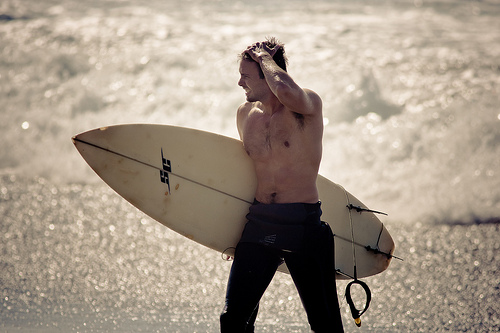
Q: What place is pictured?
A: It is an ocean.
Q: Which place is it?
A: It is an ocean.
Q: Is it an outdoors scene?
A: Yes, it is outdoors.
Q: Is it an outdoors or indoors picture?
A: It is outdoors.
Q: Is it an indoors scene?
A: No, it is outdoors.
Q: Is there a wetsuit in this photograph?
A: Yes, there is a wetsuit.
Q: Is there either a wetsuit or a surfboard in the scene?
A: Yes, there is a wetsuit.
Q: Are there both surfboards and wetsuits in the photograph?
A: Yes, there are both a wetsuit and a surfboard.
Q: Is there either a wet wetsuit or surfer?
A: Yes, there is a wet wetsuit.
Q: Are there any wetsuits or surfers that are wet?
A: Yes, the wetsuit is wet.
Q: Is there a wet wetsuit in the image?
A: Yes, there is a wet wetsuit.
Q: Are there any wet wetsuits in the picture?
A: Yes, there is a wet wetsuit.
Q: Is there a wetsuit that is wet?
A: Yes, there is a wetsuit that is wet.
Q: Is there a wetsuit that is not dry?
A: Yes, there is a wet wetsuit.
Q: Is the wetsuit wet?
A: Yes, the wetsuit is wet.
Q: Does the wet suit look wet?
A: Yes, the wet suit is wet.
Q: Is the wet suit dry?
A: No, the wet suit is wet.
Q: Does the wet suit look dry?
A: No, the wet suit is wet.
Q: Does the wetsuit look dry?
A: No, the wetsuit is wet.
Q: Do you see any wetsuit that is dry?
A: No, there is a wetsuit but it is wet.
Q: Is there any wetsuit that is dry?
A: No, there is a wetsuit but it is wet.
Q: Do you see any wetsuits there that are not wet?
A: No, there is a wetsuit but it is wet.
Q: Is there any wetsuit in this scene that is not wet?
A: No, there is a wetsuit but it is wet.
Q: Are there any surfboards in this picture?
A: Yes, there is a surfboard.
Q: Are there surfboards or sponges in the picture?
A: Yes, there is a surfboard.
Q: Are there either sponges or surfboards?
A: Yes, there is a surfboard.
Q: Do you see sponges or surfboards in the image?
A: Yes, there is a surfboard.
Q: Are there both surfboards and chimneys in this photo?
A: No, there is a surfboard but no chimneys.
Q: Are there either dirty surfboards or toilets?
A: Yes, there is a dirty surfboard.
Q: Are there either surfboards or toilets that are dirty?
A: Yes, the surfboard is dirty.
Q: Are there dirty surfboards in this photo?
A: Yes, there is a dirty surfboard.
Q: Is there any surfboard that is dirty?
A: Yes, there is a surfboard that is dirty.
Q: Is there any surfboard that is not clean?
A: Yes, there is a dirty surfboard.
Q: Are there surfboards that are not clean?
A: Yes, there is a dirty surfboard.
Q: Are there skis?
A: No, there are no skis.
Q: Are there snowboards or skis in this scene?
A: No, there are no skis or snowboards.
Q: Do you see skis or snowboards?
A: No, there are no skis or snowboards.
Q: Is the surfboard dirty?
A: Yes, the surfboard is dirty.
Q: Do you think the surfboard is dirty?
A: Yes, the surfboard is dirty.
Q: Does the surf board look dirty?
A: Yes, the surf board is dirty.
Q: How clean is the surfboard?
A: The surfboard is dirty.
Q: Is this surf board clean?
A: No, the surf board is dirty.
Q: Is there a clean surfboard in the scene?
A: No, there is a surfboard but it is dirty.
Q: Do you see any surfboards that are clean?
A: No, there is a surfboard but it is dirty.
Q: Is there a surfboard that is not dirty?
A: No, there is a surfboard but it is dirty.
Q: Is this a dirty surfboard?
A: Yes, this is a dirty surfboard.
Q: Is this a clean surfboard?
A: No, this is a dirty surfboard.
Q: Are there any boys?
A: No, there are no boys.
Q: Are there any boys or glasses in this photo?
A: No, there are no boys or glasses.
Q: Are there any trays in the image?
A: No, there are no trays.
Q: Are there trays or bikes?
A: No, there are no trays or bikes.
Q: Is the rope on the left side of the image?
A: No, the rope is on the right of the image.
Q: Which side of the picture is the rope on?
A: The rope is on the right of the image.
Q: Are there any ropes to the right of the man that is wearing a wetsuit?
A: Yes, there is a rope to the right of the man.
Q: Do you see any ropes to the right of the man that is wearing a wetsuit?
A: Yes, there is a rope to the right of the man.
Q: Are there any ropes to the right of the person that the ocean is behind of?
A: Yes, there is a rope to the right of the man.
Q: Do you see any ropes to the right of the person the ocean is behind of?
A: Yes, there is a rope to the right of the man.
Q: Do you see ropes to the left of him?
A: No, the rope is to the right of the man.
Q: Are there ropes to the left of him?
A: No, the rope is to the right of the man.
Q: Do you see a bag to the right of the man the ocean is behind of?
A: No, there is a rope to the right of the man.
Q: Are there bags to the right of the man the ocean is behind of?
A: No, there is a rope to the right of the man.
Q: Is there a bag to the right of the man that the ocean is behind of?
A: No, there is a rope to the right of the man.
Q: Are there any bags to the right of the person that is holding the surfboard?
A: No, there is a rope to the right of the man.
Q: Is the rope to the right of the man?
A: Yes, the rope is to the right of the man.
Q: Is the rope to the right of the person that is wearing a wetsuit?
A: Yes, the rope is to the right of the man.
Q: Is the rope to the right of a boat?
A: No, the rope is to the right of the man.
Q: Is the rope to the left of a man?
A: No, the rope is to the right of a man.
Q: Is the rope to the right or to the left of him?
A: The rope is to the right of the man.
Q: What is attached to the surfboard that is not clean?
A: The rope is attached to the surfboard.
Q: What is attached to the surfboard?
A: The rope is attached to the surfboard.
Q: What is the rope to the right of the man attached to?
A: The rope is attached to the surfboard.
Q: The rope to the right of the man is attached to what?
A: The rope is attached to the surfboard.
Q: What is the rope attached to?
A: The rope is attached to the surfboard.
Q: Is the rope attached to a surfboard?
A: Yes, the rope is attached to a surfboard.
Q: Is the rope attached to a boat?
A: No, the rope is attached to a surfboard.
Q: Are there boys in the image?
A: No, there are no boys.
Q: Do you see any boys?
A: No, there are no boys.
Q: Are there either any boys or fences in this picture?
A: No, there are no boys or fences.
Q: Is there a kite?
A: No, there are no kites.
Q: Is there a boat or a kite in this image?
A: No, there are no kites or boats.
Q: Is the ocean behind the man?
A: Yes, the ocean is behind the man.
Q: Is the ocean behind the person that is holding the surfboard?
A: Yes, the ocean is behind the man.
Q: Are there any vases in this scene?
A: No, there are no vases.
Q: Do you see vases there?
A: No, there are no vases.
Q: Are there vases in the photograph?
A: No, there are no vases.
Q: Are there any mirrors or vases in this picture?
A: No, there are no vases or mirrors.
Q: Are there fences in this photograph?
A: No, there are no fences.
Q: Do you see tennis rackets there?
A: No, there are no tennis rackets.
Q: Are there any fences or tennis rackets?
A: No, there are no tennis rackets or fences.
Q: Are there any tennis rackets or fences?
A: No, there are no tennis rackets or fences.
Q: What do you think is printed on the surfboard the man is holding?
A: The logo is printed on the surfboard.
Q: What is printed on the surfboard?
A: The logo is printed on the surfboard.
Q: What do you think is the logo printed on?
A: The logo is printed on the surfboard.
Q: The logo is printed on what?
A: The logo is printed on the surfboard.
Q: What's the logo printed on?
A: The logo is printed on the surfboard.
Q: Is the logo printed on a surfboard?
A: Yes, the logo is printed on a surfboard.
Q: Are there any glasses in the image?
A: No, there are no glasses.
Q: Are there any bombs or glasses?
A: No, there are no glasses or bombs.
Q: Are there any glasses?
A: No, there are no glasses.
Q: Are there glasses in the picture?
A: No, there are no glasses.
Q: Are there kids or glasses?
A: No, there are no glasses or kids.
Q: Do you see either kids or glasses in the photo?
A: No, there are no glasses or kids.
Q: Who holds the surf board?
A: The man holds the surf board.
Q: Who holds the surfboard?
A: The man holds the surf board.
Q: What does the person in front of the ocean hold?
A: The man holds the surfboard.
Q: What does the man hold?
A: The man holds the surfboard.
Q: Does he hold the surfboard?
A: Yes, the man holds the surfboard.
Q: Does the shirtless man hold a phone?
A: No, the man holds the surfboard.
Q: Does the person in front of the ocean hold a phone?
A: No, the man holds the surfboard.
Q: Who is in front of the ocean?
A: The man is in front of the ocean.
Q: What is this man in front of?
A: The man is in front of the ocean.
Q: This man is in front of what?
A: The man is in front of the ocean.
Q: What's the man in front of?
A: The man is in front of the ocean.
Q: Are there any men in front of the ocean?
A: Yes, there is a man in front of the ocean.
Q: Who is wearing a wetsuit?
A: The man is wearing a wetsuit.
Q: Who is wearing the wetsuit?
A: The man is wearing a wetsuit.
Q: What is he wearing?
A: The man is wearing a wet suit.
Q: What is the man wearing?
A: The man is wearing a wet suit.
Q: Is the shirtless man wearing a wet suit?
A: Yes, the man is wearing a wet suit.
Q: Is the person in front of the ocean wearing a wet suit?
A: Yes, the man is wearing a wet suit.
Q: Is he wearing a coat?
A: No, the man is wearing a wet suit.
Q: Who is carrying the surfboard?
A: The man is carrying the surfboard.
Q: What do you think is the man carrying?
A: The man is carrying a surfboard.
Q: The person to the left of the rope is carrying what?
A: The man is carrying a surfboard.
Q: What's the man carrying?
A: The man is carrying a surfboard.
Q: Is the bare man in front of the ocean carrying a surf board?
A: Yes, the man is carrying a surf board.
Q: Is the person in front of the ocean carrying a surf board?
A: Yes, the man is carrying a surf board.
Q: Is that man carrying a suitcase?
A: No, the man is carrying a surf board.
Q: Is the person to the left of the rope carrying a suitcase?
A: No, the man is carrying a surf board.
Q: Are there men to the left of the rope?
A: Yes, there is a man to the left of the rope.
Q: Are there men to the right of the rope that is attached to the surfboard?
A: No, the man is to the left of the rope.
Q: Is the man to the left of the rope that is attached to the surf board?
A: Yes, the man is to the left of the rope.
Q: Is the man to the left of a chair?
A: No, the man is to the left of the rope.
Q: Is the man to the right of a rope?
A: No, the man is to the left of a rope.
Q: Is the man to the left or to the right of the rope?
A: The man is to the left of the rope.